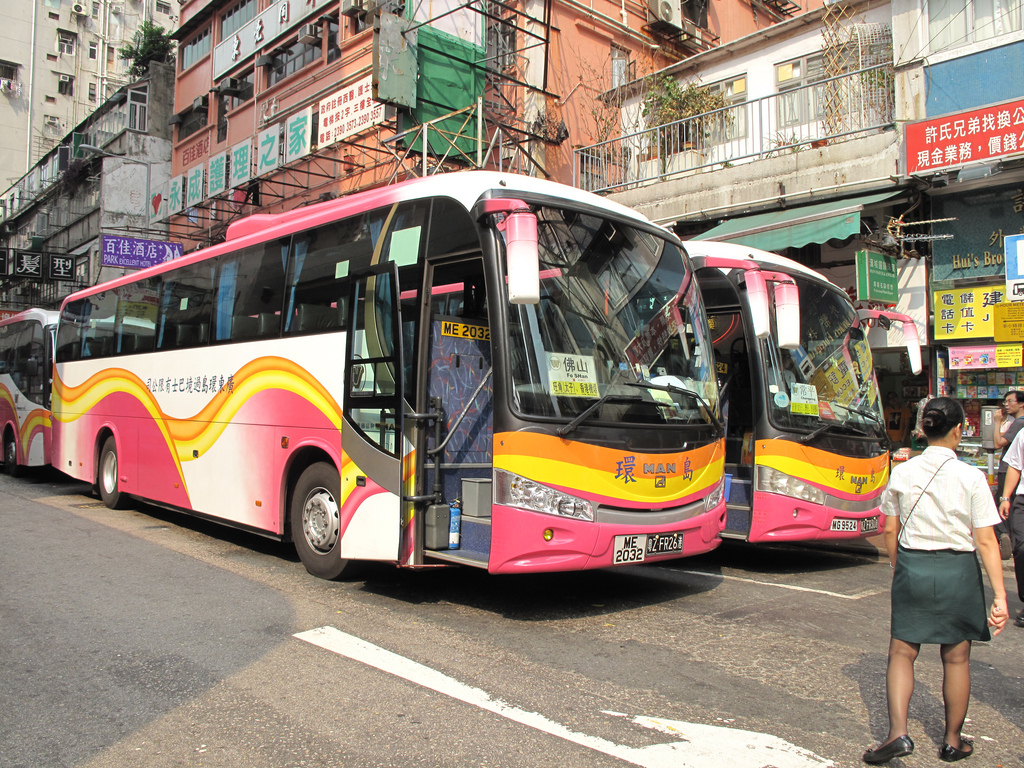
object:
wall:
[591, 0, 922, 228]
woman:
[862, 397, 1009, 764]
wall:
[170, 0, 550, 237]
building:
[169, 0, 832, 255]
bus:
[49, 170, 725, 581]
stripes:
[50, 356, 338, 462]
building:
[570, 0, 1021, 488]